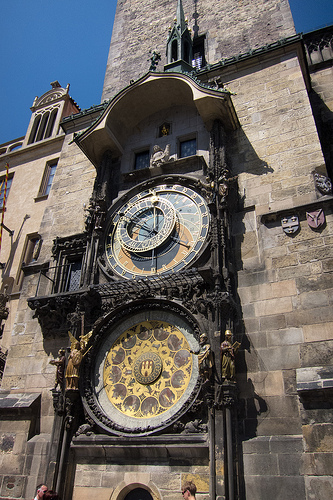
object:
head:
[179, 480, 198, 497]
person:
[181, 480, 199, 499]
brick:
[252, 295, 293, 318]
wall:
[1, 53, 331, 500]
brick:
[302, 324, 332, 344]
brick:
[265, 325, 307, 347]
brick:
[240, 454, 280, 476]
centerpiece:
[133, 351, 162, 386]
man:
[218, 328, 241, 383]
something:
[231, 340, 241, 354]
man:
[30, 482, 51, 500]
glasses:
[36, 486, 48, 494]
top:
[182, 482, 196, 498]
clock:
[94, 174, 214, 280]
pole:
[0, 161, 9, 266]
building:
[0, 0, 332, 500]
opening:
[110, 483, 157, 498]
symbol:
[156, 387, 179, 409]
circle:
[77, 298, 209, 440]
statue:
[64, 330, 96, 393]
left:
[50, 296, 135, 433]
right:
[161, 300, 231, 437]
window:
[176, 131, 197, 158]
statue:
[148, 142, 178, 167]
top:
[118, 153, 207, 182]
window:
[47, 107, 60, 140]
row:
[27, 103, 61, 143]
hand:
[147, 187, 160, 231]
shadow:
[225, 93, 273, 444]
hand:
[116, 209, 154, 232]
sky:
[0, 0, 332, 148]